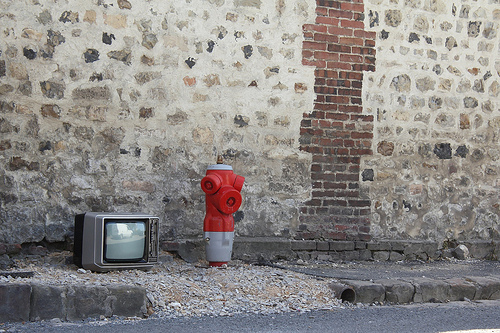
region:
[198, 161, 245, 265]
A red and gray fire hydrant.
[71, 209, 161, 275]
A small old television.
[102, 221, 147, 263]
Gray screen of a small television.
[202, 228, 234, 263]
Bottom gray strip on a red fire hydrant.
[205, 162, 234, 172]
Top gray cap on a red fire hydrant.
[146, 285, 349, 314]
Busted up concrete coming down onto the road.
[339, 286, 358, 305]
The end of a pipe in the road.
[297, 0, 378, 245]
Section of brick wall coming down.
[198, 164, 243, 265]
A gray and red fire hydrant.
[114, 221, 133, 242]
White reflection on the television screen.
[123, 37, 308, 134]
the wall has dots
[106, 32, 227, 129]
the wall has dots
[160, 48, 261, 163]
the wall has dots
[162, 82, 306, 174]
the wall has dots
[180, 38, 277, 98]
the wall has dots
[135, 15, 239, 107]
the wall has dots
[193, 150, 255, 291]
the tube is orange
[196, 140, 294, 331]
the tube is orange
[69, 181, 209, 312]
the tv is old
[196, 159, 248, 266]
this is a hydrant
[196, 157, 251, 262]
the hydrant is red and white in color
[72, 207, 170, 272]
this is a television set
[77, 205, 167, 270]
the television set is off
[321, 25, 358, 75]
the wall is made of bricks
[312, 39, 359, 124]
the wall is old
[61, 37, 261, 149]
the wall is of stones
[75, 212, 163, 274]
the television is old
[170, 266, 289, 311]
the floor is dirty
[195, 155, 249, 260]
the hydrant is short